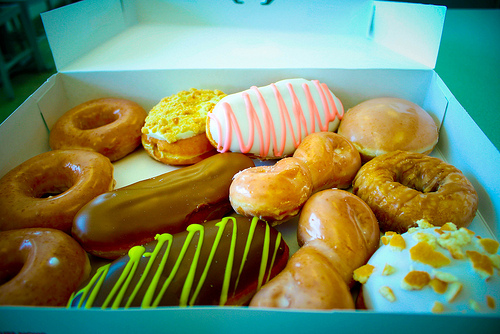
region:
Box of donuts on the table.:
[0, 59, 497, 331]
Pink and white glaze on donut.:
[204, 75, 334, 149]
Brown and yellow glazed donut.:
[73, 210, 275, 312]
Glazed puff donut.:
[347, 86, 445, 156]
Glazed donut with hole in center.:
[47, 96, 152, 159]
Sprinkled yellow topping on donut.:
[141, 80, 207, 164]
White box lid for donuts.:
[34, 1, 456, 73]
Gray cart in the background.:
[2, 3, 44, 91]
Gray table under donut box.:
[450, 10, 499, 80]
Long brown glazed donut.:
[80, 146, 257, 242]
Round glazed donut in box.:
[60, 98, 150, 157]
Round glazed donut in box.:
[35, 145, 94, 209]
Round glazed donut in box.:
[12, 225, 102, 315]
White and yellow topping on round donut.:
[152, 88, 207, 172]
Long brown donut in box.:
[107, 168, 222, 210]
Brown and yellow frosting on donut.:
[92, 243, 270, 297]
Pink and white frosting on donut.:
[218, 85, 322, 133]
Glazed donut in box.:
[248, 145, 341, 198]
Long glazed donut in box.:
[293, 179, 344, 306]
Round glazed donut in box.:
[346, 87, 441, 165]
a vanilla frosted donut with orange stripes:
[206, 75, 342, 147]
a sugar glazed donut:
[252, 185, 372, 310]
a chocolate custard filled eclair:
[72, 152, 245, 252]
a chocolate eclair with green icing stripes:
[73, 218, 288, 305]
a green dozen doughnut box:
[1, 313, 498, 330]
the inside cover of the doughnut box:
[41, 0, 446, 71]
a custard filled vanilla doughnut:
[363, 223, 498, 319]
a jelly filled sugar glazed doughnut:
[343, 93, 440, 154]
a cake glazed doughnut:
[359, 148, 480, 229]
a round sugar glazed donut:
[49, 95, 144, 154]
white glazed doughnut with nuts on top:
[361, 210, 498, 318]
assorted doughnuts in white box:
[17, 77, 499, 309]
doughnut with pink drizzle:
[190, 66, 347, 156]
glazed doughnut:
[36, 77, 139, 158]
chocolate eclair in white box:
[60, 135, 263, 252]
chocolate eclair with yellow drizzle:
[64, 198, 299, 314]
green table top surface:
[453, 19, 498, 79]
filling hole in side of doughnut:
[144, 137, 175, 164]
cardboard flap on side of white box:
[26, 69, 73, 131]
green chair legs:
[0, 4, 52, 96]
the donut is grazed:
[342, 93, 464, 160]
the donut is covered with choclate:
[101, 167, 242, 210]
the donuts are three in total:
[43, 104, 114, 301]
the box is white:
[98, 36, 415, 77]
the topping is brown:
[379, 223, 477, 298]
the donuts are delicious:
[33, 96, 473, 306]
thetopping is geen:
[115, 236, 278, 301]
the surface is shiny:
[364, 99, 437, 142]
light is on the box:
[157, 33, 296, 63]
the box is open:
[26, 2, 496, 317]